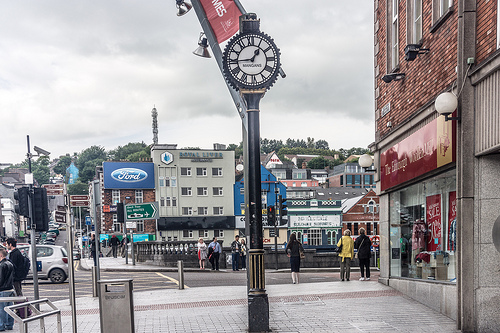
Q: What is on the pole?
A: Clock.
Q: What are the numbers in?
A: Roman.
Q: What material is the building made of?
A: Brick.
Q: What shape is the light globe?
A: Round.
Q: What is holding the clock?
A: A post.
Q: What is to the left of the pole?
A: Trash Can.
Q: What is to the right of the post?
A: A Building.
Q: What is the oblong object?
A: A post.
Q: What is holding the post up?
A: Concrete.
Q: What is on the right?
A: Storefront.